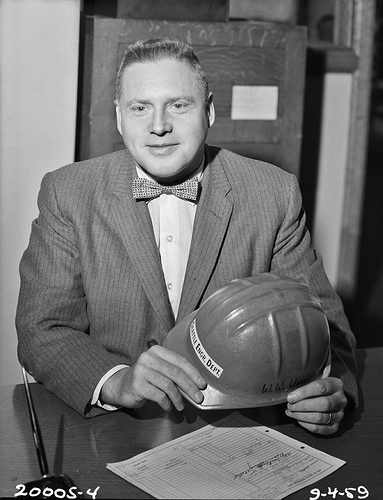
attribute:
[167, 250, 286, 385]
helmet — held, labeled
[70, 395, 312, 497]
paper — white, written, printed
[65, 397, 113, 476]
table — here, shaded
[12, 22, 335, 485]
picture — dated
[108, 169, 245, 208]
tie — worn, squared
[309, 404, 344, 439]
ring — worn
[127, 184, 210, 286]
shirt — buttoned, white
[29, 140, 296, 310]
suit — worn, striped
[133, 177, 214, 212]
bow — lovely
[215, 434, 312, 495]
lettering — black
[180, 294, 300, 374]
hat — hard, held, written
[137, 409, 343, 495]
invoice — white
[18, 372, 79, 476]
pen — old, held, cased, upright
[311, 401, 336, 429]
band — tasteful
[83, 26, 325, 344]
man — reflected, smiling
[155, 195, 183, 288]
buttons — small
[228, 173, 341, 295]
jacket — striped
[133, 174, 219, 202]
bow tie — checked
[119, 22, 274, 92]
hair — short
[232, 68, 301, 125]
label — printed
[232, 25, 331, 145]
box — wooden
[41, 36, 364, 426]
photo — black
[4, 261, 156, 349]
blazer — striped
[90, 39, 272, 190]
head — large